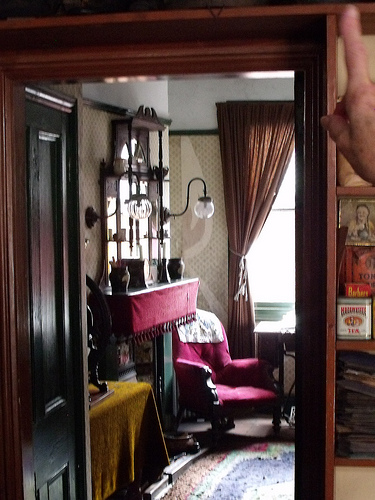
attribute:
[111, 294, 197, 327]
cloth — red, fringed, hung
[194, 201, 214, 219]
bulb — round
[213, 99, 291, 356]
curtain — brown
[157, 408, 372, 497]
ground — carpet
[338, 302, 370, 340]
container — metalic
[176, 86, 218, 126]
wall — white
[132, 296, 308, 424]
chair — red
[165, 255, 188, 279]
vase — round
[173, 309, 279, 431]
chair — empty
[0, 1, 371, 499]
room — old fashioned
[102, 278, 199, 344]
cloth — red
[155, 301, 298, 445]
chair — red, arm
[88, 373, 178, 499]
cloth — table, yellow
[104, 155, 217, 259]
poles — curved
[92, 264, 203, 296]
top — mantle